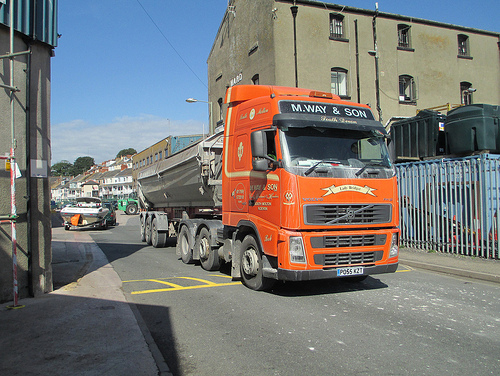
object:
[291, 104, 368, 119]
white letter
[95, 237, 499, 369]
street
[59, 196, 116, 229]
boat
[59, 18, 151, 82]
sky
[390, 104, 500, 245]
buses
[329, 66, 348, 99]
windows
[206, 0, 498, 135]
building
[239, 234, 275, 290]
tire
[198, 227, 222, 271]
tire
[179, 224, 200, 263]
tire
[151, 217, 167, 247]
tire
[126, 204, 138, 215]
tire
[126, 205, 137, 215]
wheel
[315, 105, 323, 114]
letter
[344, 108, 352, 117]
letter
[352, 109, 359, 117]
letter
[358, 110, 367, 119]
letter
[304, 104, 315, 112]
letter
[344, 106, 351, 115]
letter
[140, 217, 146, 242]
tires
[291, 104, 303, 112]
letter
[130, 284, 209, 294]
yellow lines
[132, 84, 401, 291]
large truck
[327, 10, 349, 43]
window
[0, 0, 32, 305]
scaffolding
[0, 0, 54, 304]
side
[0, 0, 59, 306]
building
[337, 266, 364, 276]
license plate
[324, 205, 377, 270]
vents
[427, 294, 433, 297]
spots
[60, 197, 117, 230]
car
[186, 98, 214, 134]
street light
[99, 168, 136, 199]
building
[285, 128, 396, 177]
windshield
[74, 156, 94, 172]
trees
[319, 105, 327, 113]
letter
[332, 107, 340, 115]
letter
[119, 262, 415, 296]
crosswalk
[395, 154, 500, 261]
fence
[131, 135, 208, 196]
building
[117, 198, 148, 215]
towing trailer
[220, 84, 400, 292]
cab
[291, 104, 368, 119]
sign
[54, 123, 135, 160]
clouds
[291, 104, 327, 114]
m.way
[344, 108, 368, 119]
son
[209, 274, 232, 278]
line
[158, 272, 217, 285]
line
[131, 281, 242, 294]
line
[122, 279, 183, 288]
line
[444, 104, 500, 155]
bin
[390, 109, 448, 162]
bin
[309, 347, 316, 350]
spot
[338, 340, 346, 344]
spot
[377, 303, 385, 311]
spot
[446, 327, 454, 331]
spot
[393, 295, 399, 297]
spot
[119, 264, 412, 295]
speedbump